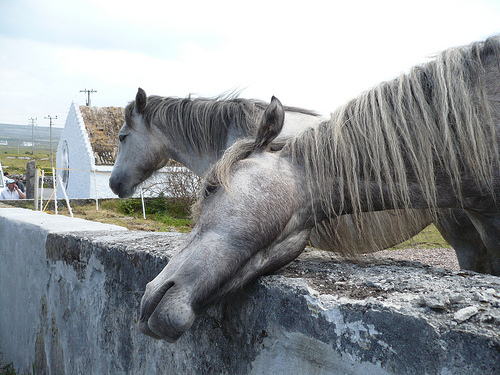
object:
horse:
[108, 86, 500, 276]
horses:
[109, 30, 499, 343]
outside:
[0, 8, 49, 156]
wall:
[0, 221, 500, 375]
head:
[142, 96, 323, 342]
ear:
[254, 94, 286, 156]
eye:
[117, 129, 130, 144]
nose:
[111, 174, 122, 193]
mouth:
[144, 277, 180, 343]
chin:
[160, 305, 198, 339]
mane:
[354, 94, 422, 231]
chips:
[433, 292, 479, 330]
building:
[57, 103, 199, 201]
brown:
[93, 110, 113, 156]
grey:
[7, 241, 39, 280]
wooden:
[50, 121, 55, 180]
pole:
[30, 114, 34, 163]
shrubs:
[161, 172, 189, 216]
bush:
[122, 201, 135, 214]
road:
[87, 210, 138, 222]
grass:
[157, 212, 181, 224]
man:
[0, 179, 25, 202]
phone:
[13, 181, 17, 187]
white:
[72, 153, 89, 173]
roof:
[78, 106, 184, 166]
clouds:
[239, 6, 295, 59]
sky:
[0, 0, 500, 117]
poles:
[26, 115, 57, 145]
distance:
[4, 98, 58, 171]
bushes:
[122, 199, 163, 212]